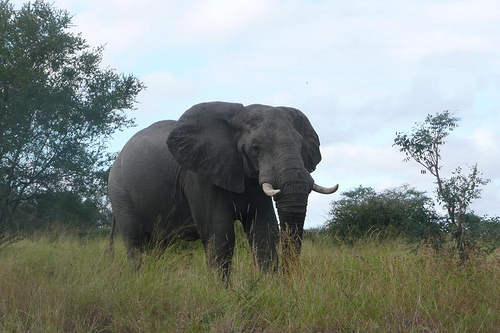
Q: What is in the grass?
A: Elephant.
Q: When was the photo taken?
A: During the daytime.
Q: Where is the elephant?
A: In the wilderness.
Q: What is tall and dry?
A: The grass.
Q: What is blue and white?
A: The sky.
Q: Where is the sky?
A: Above the land.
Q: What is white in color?
A: The tusks.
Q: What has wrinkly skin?
A: The elephant.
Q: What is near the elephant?
A: Trees.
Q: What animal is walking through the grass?
A: Elephant.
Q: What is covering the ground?
A: Grass.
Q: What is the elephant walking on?
A: Grass.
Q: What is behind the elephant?
A: Tree.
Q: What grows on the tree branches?
A: Leaves.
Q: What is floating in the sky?
A: Clouds.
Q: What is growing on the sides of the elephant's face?
A: Tusks.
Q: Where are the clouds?
A: In the sky.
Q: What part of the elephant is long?
A: Trunk.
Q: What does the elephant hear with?
A: Ears.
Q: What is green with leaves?
A: Tree.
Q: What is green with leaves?
A: Tree.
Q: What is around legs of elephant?
A: Grass.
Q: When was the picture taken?
A: During the day.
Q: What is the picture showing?
A: An elephant.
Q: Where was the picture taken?
A: In the wild.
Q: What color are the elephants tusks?
A: White.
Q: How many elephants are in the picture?
A: One.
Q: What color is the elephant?
A: Gray.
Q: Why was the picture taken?
A: To capture the elephant.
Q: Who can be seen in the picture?
A: No one.